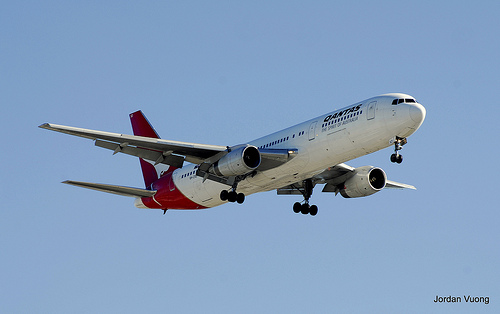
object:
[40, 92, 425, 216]
airplane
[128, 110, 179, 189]
tail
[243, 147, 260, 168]
intake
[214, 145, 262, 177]
engine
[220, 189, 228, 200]
wheels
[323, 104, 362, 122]
logo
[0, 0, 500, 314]
sky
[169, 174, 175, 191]
door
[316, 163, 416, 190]
right wing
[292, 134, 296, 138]
passenger windows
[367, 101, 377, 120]
door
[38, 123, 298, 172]
left wing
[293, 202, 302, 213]
wheels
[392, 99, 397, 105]
windshield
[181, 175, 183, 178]
windows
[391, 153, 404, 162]
wheels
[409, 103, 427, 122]
nose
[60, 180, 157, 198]
rear wing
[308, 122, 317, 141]
passenger door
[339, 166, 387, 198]
engine